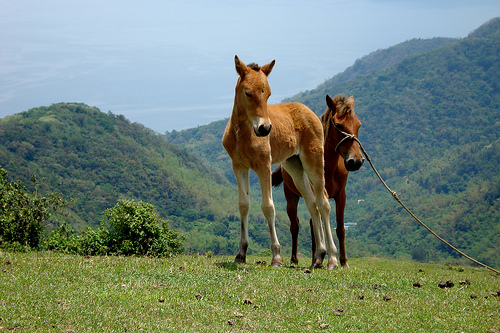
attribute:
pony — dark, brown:
[220, 55, 340, 272]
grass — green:
[4, 241, 498, 329]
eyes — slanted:
[234, 84, 360, 138]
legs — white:
[301, 151, 337, 265]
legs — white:
[283, 162, 327, 269]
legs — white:
[248, 161, 283, 265]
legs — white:
[230, 165, 252, 262]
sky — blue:
[3, 5, 498, 137]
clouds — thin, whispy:
[2, 5, 495, 127]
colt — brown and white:
[156, 59, 341, 257]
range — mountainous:
[5, 17, 497, 267]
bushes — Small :
[0, 181, 180, 257]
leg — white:
[219, 157, 259, 273]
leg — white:
[253, 162, 292, 270]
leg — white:
[279, 147, 334, 276]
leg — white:
[298, 145, 343, 276]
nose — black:
[257, 122, 272, 137]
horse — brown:
[224, 52, 337, 265]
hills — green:
[2, 4, 498, 244]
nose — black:
[342, 154, 371, 166]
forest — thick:
[219, 26, 496, 273]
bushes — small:
[0, 164, 190, 255]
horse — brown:
[270, 90, 360, 267]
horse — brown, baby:
[322, 93, 377, 255]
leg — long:
[257, 151, 282, 276]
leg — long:
[228, 163, 259, 267]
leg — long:
[295, 136, 343, 271]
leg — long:
[285, 161, 330, 273]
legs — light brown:
[203, 146, 359, 272]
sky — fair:
[3, 2, 496, 67]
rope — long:
[360, 141, 488, 269]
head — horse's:
[325, 95, 362, 164]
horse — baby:
[319, 95, 386, 292]